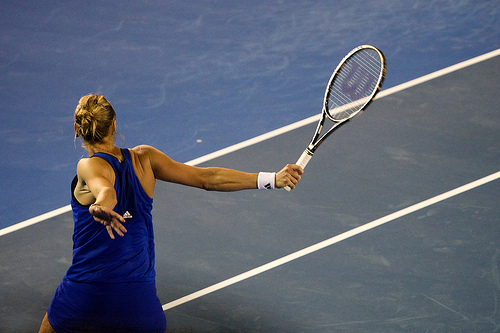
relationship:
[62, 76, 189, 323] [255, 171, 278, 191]
player wearing white wrist wristband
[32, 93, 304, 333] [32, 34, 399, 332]
player plays tennis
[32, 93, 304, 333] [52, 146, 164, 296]
player wears shirt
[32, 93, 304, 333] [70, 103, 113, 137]
player has hair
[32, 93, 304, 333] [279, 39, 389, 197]
player holds racket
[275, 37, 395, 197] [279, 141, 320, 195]
tennis racket has handle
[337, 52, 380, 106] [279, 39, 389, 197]
w on racket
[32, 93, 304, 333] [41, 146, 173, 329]
player wears outfit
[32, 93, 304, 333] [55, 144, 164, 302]
player wears top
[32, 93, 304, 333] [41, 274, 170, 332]
player wears shorts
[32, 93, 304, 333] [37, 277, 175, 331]
player wears shorts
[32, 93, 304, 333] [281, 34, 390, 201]
player holds tennis racket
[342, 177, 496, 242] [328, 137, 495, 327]
lines on ground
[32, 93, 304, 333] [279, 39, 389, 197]
player holding a tenn racket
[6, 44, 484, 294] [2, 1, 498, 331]
lines on ground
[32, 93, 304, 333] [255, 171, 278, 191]
player wearing a wristband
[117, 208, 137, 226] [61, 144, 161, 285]
logo on shirt